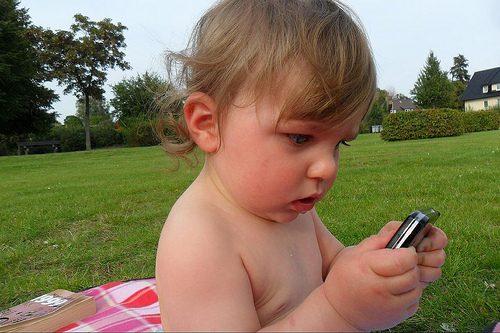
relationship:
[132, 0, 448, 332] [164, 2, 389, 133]
baby has messy hair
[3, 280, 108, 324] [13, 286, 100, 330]
cover attached to book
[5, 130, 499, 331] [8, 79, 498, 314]
grass covering yard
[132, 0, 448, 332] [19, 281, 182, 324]
baby sitting on top of blanket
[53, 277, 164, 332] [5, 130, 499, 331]
blanket on grass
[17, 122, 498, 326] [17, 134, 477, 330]
grass covering ground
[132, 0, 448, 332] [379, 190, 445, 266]
baby holding phone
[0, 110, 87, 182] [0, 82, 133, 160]
bench next to hedge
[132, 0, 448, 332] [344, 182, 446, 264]
baby holding cellphone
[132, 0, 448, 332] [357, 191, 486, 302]
baby looking at cellphone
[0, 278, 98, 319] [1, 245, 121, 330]
title on book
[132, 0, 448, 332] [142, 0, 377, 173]
baby has messy hair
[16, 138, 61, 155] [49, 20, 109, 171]
bench next to tree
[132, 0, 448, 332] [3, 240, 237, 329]
baby sitting on blanket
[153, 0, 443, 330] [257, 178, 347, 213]
baby has lip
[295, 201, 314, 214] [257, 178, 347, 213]
drowl on lip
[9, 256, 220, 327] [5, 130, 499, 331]
banket in grass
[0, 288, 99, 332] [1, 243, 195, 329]
book on blanket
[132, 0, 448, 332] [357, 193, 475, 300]
baby looking at phone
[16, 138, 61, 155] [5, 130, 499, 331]
bench on grass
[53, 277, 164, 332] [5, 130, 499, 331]
blanket in grass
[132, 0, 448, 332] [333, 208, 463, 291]
baby has a phone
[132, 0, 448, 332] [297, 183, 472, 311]
baby has hand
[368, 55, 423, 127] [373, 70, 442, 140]
home with a roof